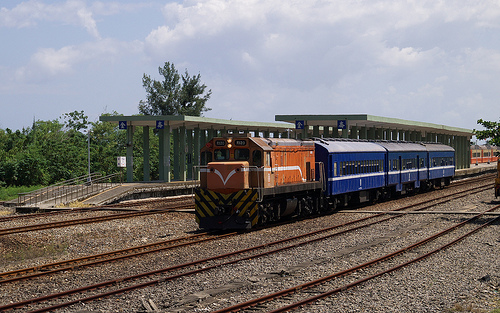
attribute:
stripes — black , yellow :
[186, 182, 263, 234]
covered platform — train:
[107, 104, 472, 184]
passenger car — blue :
[183, 106, 463, 238]